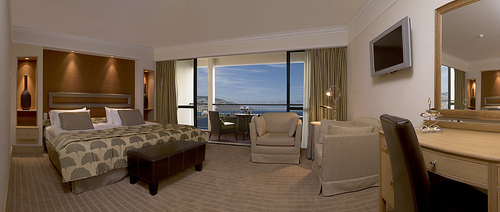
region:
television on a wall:
[356, 11, 421, 93]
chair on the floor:
[238, 107, 307, 176]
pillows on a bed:
[98, 101, 157, 131]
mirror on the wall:
[426, 0, 498, 120]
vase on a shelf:
[17, 71, 34, 116]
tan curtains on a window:
[150, 54, 181, 129]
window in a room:
[171, 44, 310, 145]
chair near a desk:
[372, 100, 461, 210]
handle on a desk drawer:
[425, 155, 440, 172]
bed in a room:
[36, 101, 217, 197]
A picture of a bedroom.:
[8, 7, 481, 204]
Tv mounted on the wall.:
[365, 17, 415, 78]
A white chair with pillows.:
[247, 98, 307, 171]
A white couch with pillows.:
[310, 110, 379, 198]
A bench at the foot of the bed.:
[118, 130, 223, 198]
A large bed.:
[47, 102, 206, 195]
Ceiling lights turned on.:
[47, 39, 131, 86]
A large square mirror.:
[431, 0, 498, 127]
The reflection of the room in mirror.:
[442, 17, 496, 105]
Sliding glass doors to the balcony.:
[179, 57, 304, 142]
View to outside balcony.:
[196, 58, 310, 139]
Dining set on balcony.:
[206, 102, 261, 143]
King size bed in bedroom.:
[44, 106, 213, 193]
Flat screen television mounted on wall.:
[358, 12, 418, 84]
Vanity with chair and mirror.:
[378, 108, 498, 210]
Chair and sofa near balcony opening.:
[248, 106, 381, 199]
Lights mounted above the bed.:
[61, 46, 130, 81]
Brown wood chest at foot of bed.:
[128, 136, 215, 188]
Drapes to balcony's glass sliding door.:
[306, 49, 353, 160]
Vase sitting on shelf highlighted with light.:
[16, 58, 34, 120]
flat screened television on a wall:
[356, 16, 423, 80]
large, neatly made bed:
[46, 92, 203, 196]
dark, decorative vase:
[16, 67, 37, 116]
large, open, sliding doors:
[170, 49, 324, 151]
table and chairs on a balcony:
[206, 100, 278, 142]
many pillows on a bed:
[47, 100, 148, 132]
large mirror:
[432, 0, 495, 117]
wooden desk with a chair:
[367, 100, 499, 210]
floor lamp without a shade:
[323, 77, 346, 141]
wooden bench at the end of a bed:
[123, 127, 209, 202]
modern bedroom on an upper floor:
[0, 0, 497, 210]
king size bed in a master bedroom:
[44, 109, 207, 191]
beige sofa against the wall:
[308, 116, 380, 193]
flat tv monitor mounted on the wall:
[368, 15, 413, 77]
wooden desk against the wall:
[379, 126, 499, 210]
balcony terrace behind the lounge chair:
[175, 50, 304, 142]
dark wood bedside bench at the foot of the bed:
[125, 139, 205, 195]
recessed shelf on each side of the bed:
[15, 55, 35, 124]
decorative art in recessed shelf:
[20, 73, 31, 109]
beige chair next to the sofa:
[248, 111, 303, 163]